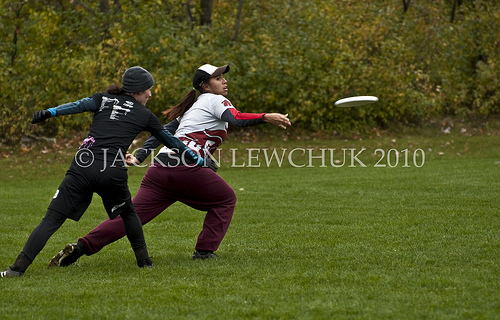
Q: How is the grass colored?
A: Green.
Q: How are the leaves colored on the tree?
A: Green.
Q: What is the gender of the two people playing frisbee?
A: Female.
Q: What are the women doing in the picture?
A: Playing with a frisbee.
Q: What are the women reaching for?
A: Frisbee.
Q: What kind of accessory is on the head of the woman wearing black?
A: Beanie.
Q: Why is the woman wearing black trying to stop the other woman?
A: She is playing defense.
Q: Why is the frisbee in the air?
A: It was thrown.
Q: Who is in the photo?
A: Two women.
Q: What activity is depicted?
A: Playing with a frisbee.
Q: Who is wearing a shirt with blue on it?
A: The woman on the left.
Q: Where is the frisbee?
A: In the air.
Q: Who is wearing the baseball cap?
A: The woman wearing the white shirt.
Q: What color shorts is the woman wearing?
A: Black.